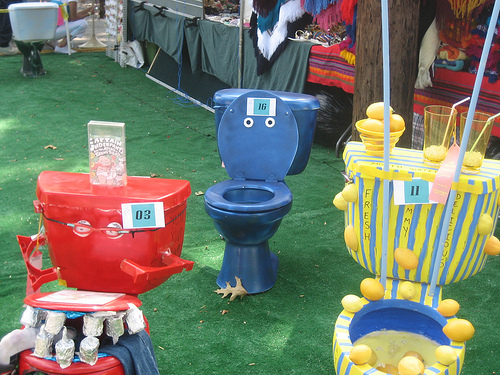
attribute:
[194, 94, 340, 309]
toilet — blue